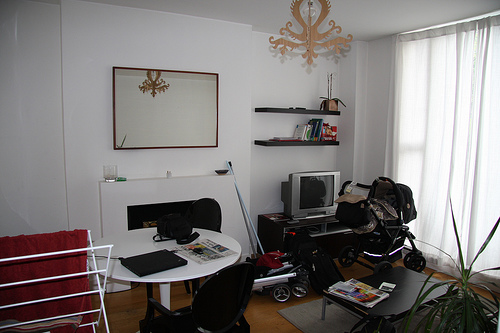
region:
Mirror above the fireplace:
[111, 66, 221, 152]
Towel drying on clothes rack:
[3, 226, 113, 329]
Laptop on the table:
[121, 245, 188, 276]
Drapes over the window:
[389, 20, 496, 270]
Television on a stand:
[281, 169, 341, 219]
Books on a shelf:
[293, 119, 324, 145]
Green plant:
[356, 197, 495, 331]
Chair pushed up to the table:
[137, 261, 262, 331]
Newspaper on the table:
[178, 239, 235, 265]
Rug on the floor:
[278, 272, 498, 332]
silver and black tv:
[275, 166, 349, 224]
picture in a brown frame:
[100, 66, 225, 157]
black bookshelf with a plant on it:
[252, 69, 344, 121]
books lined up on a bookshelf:
[250, 109, 345, 152]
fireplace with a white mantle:
[92, 166, 242, 243]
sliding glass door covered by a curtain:
[391, 19, 496, 279]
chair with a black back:
[140, 256, 262, 332]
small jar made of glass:
[97, 159, 123, 186]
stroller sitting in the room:
[327, 170, 437, 280]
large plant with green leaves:
[398, 189, 498, 331]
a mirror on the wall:
[112, 65, 218, 149]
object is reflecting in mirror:
[138, 68, 168, 98]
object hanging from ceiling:
[270, 1, 351, 68]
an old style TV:
[280, 170, 340, 215]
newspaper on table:
[175, 239, 232, 261]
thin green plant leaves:
[409, 196, 499, 331]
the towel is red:
[0, 228, 90, 319]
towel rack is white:
[2, 230, 113, 332]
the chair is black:
[139, 264, 250, 331]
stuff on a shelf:
[266, 118, 338, 140]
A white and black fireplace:
[105, 163, 251, 298]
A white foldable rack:
[7, 220, 116, 332]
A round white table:
[87, 214, 249, 304]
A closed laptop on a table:
[109, 230, 193, 298]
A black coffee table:
[321, 255, 473, 327]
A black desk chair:
[138, 260, 275, 329]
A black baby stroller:
[330, 165, 427, 280]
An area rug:
[278, 282, 378, 332]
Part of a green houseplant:
[377, 210, 497, 331]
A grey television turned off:
[273, 160, 340, 215]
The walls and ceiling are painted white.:
[0, 0, 499, 291]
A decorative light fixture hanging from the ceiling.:
[266, 0, 354, 68]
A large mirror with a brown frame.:
[110, 65, 219, 150]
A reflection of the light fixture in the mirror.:
[138, 70, 169, 99]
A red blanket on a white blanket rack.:
[0, 226, 113, 331]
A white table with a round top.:
[88, 225, 239, 330]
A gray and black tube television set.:
[278, 170, 341, 223]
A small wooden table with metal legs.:
[317, 264, 453, 330]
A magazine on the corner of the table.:
[325, 275, 387, 307]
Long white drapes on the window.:
[381, 13, 498, 290]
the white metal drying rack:
[3, 230, 113, 330]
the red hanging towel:
[2, 230, 89, 317]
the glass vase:
[103, 165, 117, 183]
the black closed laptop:
[120, 249, 189, 274]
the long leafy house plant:
[384, 197, 499, 332]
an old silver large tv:
[277, 166, 337, 219]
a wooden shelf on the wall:
[255, 138, 340, 147]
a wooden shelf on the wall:
[254, 106, 344, 116]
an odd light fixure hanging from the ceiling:
[268, 2, 354, 66]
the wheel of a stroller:
[405, 250, 425, 272]